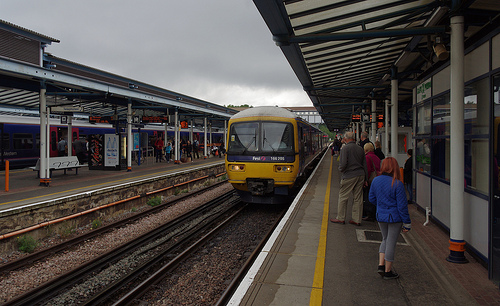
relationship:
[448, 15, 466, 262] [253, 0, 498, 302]
white pole for building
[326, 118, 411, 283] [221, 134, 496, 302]
people standing on platform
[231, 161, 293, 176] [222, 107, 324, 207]
lights are in train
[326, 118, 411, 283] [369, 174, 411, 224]
people in coat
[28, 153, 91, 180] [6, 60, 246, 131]
bench under awning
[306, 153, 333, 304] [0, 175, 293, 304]
line beside tracks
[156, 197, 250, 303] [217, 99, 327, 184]
train tracks beside train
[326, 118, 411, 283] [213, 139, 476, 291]
people on platform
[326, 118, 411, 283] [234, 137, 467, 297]
people at platform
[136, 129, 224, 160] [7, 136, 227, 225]
people at platform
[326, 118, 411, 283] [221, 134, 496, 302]
people at platform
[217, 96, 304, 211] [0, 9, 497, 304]
train in station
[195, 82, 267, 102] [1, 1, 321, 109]
cloud in sky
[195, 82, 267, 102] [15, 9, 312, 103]
cloud in sky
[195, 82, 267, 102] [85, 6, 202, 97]
cloud in sky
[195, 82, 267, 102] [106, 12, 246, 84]
cloud in sky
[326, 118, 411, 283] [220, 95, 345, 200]
people waiting for train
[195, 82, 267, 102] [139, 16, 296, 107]
cloud in sky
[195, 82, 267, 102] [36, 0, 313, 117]
cloud in sky